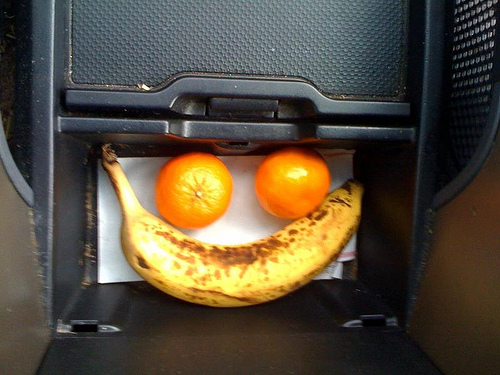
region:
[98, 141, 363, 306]
3 fruit compose an abstract smile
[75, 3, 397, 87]
rubberized dimpled grip covering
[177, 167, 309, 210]
citrus rind reflects photographer's flash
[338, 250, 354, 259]
white paper has red band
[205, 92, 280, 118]
compartment cover secures its place with a latch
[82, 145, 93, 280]
compartment bottom contains debris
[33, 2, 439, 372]
hard plastic storage compartment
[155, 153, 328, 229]
2 oranges rest on opposite axis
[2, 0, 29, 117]
dark blue carpeting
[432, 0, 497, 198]
plastic guard protects interior wall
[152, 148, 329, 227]
Two bright orange oranges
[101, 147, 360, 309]
An over ripe yellow and brown banana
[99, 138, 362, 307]
Fruit arranged in a smiley face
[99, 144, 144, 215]
Banana stem with a woody top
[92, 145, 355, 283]
White cloth behind the fruit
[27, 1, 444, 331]
Black box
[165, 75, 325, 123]
A black handle with a latch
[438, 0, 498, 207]
Round plastic piece with holes in it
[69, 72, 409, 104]
Seam in the black box with a lot of crude in it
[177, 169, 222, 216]
Light shining on an orange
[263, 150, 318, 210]
A fresh juicy orange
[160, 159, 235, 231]
A fresh juicy orange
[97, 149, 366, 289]
A yellow ripe banana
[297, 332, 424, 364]
A smooth black fridge wall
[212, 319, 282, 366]
A smooth black fridge wall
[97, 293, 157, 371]
A smooth black fridge wall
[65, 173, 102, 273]
A smooth black fridge wall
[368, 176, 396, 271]
A smooth black fridge wall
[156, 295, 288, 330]
A smooth black fridge wall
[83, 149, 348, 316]
A fruit rank in a fridge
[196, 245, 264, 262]
Brown spots on a banana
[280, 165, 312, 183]
Light shining on an orange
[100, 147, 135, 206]
Stem on a banana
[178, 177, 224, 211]
Stem on top of an orange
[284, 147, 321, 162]
Dark shadow on back of an orange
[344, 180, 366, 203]
Brown end on bottom of banana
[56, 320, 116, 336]
Hole in black metal piece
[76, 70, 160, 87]
Circle pattern on black metal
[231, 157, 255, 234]
White paper under an orange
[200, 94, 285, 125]
Button on black metal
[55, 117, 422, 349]
banana and tangerines placed in empty cubicle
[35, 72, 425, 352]
black bin with lid folded into slot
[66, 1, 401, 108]
diamond-textured black panel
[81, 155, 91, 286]
tan crumbs along the edge of container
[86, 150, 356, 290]
folded paper under the fruit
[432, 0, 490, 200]
curved panel with rows of holes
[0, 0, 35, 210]
grey rim on black curved panel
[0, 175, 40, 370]
brown wall in back of panel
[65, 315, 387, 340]
rectangular protrusions on side of container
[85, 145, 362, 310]
fruit arranged to look like a smiling face